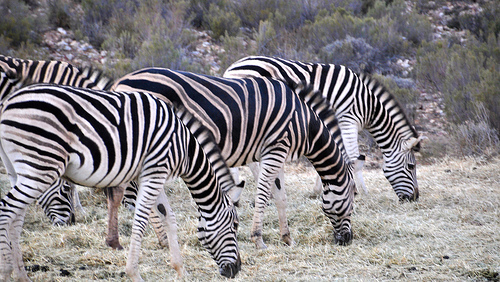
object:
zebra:
[109, 65, 359, 247]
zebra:
[0, 51, 113, 226]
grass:
[29, 153, 484, 271]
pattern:
[204, 76, 294, 153]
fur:
[219, 90, 269, 140]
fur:
[63, 99, 154, 169]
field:
[0, 149, 500, 281]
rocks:
[51, 26, 103, 64]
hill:
[0, 0, 500, 155]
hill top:
[11, 0, 473, 51]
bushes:
[0, 0, 499, 117]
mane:
[282, 80, 351, 180]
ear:
[410, 137, 424, 148]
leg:
[0, 153, 70, 281]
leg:
[103, 189, 124, 247]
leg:
[153, 206, 187, 273]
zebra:
[0, 85, 242, 282]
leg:
[274, 186, 300, 248]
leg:
[337, 120, 364, 198]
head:
[196, 209, 242, 279]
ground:
[405, 214, 468, 282]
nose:
[213, 259, 242, 279]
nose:
[330, 229, 356, 247]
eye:
[229, 219, 243, 228]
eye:
[352, 185, 361, 202]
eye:
[406, 163, 417, 170]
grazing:
[200, 157, 436, 274]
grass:
[0, 187, 499, 282]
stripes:
[150, 79, 309, 138]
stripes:
[119, 104, 179, 201]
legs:
[123, 162, 183, 279]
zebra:
[221, 55, 427, 203]